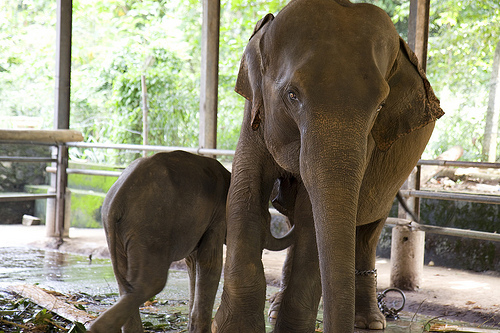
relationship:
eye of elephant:
[284, 88, 300, 103] [215, 3, 449, 328]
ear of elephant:
[235, 9, 278, 131] [215, 3, 449, 328]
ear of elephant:
[372, 19, 446, 153] [215, 3, 449, 328]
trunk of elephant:
[292, 130, 377, 332] [215, 3, 449, 328]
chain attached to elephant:
[349, 264, 408, 322] [215, 3, 449, 328]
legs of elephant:
[85, 234, 177, 332] [215, 3, 449, 328]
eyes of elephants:
[280, 84, 390, 121] [71, 3, 452, 332]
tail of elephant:
[103, 210, 139, 295] [70, 150, 233, 330]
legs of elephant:
[85, 234, 177, 332] [70, 150, 233, 330]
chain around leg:
[349, 264, 408, 322] [348, 212, 388, 327]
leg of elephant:
[348, 212, 388, 327] [215, 3, 449, 328]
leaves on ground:
[2, 286, 54, 321] [0, 230, 495, 330]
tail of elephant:
[103, 210, 139, 295] [102, 200, 128, 293]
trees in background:
[1, 2, 499, 192] [3, 2, 498, 208]